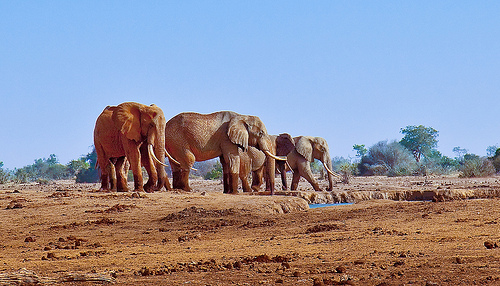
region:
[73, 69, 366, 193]
the elephants are brown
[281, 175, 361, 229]
a small body of water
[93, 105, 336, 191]
A herd of elephants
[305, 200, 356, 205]
Small oasis of water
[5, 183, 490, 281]
Arid and barren savanna desert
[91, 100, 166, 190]
Large and gray elephant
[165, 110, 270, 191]
Large and gray elephant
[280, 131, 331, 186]
Large and gray elephant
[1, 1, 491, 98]
Cloudless bright blue sky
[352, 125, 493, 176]
Trees and brush in distance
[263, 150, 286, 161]
Tusk of an elephant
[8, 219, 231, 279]
Barren savanna dirt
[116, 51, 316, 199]
this is an elephant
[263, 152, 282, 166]
this is a tusk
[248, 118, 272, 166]
the tusk is white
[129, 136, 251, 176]
the tusk is ivory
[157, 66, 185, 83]
this is a cloud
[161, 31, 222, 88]
the cloud is white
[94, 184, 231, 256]
this is a dirt ground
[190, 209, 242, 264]
the dirt is brown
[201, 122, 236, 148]
the elephant is dirty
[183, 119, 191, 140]
the elephant is brown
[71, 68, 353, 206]
Three large elephants in the jungle.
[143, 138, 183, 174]
Large tusks of an elephant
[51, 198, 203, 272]
Dirt on the ground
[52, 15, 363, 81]
A clear blue sky.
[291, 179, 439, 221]
Water in the middle of the desert.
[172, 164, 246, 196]
Wet legs of an elephant.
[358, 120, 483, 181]
Trees in the background.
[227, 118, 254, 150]
Large ear of an elephant.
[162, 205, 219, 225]
A small pile of dirt.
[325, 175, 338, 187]
Wet trunk of an elephant.